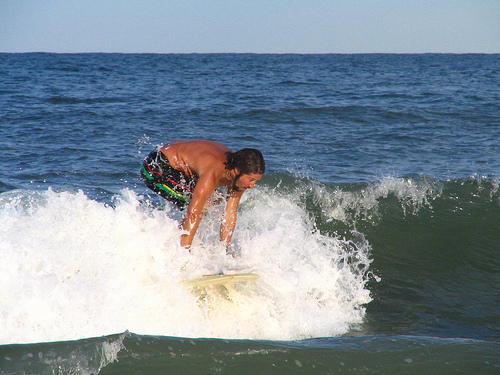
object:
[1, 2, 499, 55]
sky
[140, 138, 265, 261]
man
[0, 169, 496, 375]
wave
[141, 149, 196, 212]
trunks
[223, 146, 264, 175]
hair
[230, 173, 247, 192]
beard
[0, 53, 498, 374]
ocean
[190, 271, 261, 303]
surfboard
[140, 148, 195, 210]
stripes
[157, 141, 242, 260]
skin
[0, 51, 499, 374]
water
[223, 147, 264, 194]
head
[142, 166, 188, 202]
stripe